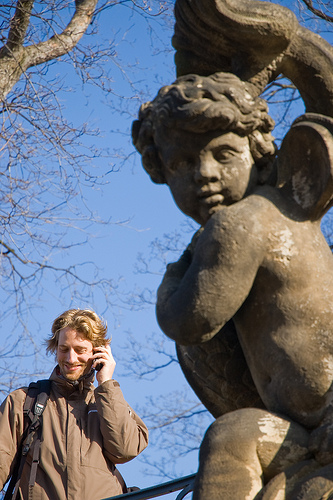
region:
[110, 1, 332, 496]
statue outside in park area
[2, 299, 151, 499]
man near the statue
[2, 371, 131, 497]
jacket on the man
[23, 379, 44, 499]
strap of bag on person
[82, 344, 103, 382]
person's phone in hand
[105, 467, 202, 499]
rail area near statue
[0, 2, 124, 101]
thick branch of tree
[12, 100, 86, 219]
thin branches on a tree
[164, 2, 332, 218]
object around head of statue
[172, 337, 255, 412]
part of object near knee of statue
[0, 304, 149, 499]
A man in a brown jacket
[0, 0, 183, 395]
A large leafless tree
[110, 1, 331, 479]
A large leafless tree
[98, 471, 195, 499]
A metal hand rail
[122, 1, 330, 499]
A stone cherub statue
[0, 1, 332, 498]
A clear, blue sky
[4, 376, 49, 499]
A blag bag strap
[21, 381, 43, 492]
A grey and brown backpack strap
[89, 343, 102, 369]
a cellphone in a person's hand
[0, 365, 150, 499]
A large brown jacket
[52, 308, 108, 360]
man has blond hair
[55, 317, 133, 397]
man is holding phone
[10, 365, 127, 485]
man has brown coat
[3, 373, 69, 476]
man has black packpack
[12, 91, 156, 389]
bare branches on trees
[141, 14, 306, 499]
carving next to man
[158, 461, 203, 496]
rail next to carving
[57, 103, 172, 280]
sky is blue and clear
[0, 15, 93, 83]
thick branches on tree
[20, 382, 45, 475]
black strap on bag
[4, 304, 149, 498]
a person on his phone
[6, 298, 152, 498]
a smiling person on his phone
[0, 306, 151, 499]
a person in brown long sleeves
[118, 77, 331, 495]
a statue with wings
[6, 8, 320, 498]
a person and a statue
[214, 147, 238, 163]
a eye of the statue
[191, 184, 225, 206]
a mouth of the statue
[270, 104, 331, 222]
wings of the statue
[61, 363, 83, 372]
a mouth of the person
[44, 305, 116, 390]
a facial expression of the guy on the phone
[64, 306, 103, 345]
Person has blonde hair.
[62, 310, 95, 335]
Person has wavy hair.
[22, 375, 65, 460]
Black strap around man's shoulder.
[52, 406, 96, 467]
Man wearing tan coat.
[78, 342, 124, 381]
Man holding cell phone in ear.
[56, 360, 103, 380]
Man has blonde facial hair.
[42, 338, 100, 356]
Man has light colored eyebrows.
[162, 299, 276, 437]
Concrete statue in front of man.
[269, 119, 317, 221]
Concrete statue has wings.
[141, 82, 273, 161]
Concrete statue has wavy hair.